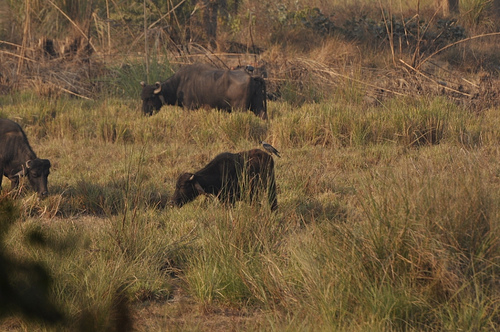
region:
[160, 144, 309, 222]
a baby steer is grazing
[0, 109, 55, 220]
an adult steer is grazing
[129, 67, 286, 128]
an adult steer is grazing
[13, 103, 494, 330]
the grasslands are dry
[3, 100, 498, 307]
the grasslands are brittle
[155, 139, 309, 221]
the baby steer stays close to family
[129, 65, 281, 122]
the adult steer stays close to the baby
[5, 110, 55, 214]
the adult steer stays close to the baby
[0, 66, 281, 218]
the steers are part of a family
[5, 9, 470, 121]
some of the brush has been trampled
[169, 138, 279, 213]
A young, grazing wildebeest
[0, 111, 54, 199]
A large, grazing wildebeest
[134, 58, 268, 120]
A large, grazing wildebeest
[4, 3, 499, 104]
A row of dry, dead branches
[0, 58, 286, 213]
A small group of wildebeest grazing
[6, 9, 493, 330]
A grassy landscape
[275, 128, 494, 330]
A patch of tall grass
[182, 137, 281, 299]
A patch of tall grass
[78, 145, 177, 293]
A patch of tall grass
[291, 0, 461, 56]
some bushes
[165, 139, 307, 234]
This is a cow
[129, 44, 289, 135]
This is a cow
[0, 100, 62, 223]
This is a cow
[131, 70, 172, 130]
Head of a cow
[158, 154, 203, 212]
Head of a cow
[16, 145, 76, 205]
Head of a cow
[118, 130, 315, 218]
A small black cow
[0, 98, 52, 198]
A big black cow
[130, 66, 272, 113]
A big black cow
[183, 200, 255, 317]
Tall dry and green grass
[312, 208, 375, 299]
Tall dry and green grass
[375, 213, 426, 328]
Tall dry and green grass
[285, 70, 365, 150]
Tall dry and green grass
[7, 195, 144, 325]
Tall dry and green grass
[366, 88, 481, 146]
Tall dry and green grass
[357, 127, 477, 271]
Tall dry and green grass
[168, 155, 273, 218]
an animal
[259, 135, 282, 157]
a small bird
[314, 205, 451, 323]
the tall grass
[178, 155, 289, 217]
the animal is brown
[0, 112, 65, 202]
the animal is eating the grass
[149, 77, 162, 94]
horn on the animal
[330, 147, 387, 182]
the grass is short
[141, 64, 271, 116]
the animal is standing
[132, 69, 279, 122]
the animal is black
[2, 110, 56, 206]
the animal is eating